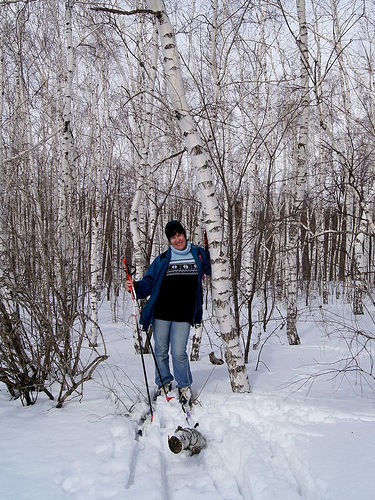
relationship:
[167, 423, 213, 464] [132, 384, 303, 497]
tree protruding from snow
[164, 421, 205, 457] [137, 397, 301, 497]
log sticking out of snow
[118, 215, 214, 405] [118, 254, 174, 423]
woman holding ski poles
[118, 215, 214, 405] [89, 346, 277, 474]
woman on snow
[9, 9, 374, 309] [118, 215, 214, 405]
trees surround woman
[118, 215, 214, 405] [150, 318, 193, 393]
woman wears blue jeans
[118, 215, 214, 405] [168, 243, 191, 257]
woman has turtle neck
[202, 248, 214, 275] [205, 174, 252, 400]
arm on tree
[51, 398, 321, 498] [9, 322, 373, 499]
snow on ground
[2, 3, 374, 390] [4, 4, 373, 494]
wooded area in picture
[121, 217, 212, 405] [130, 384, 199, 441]
she on skis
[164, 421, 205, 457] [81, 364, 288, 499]
log on ground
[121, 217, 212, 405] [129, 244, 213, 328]
she wears coat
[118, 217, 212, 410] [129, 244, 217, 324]
she wears sweater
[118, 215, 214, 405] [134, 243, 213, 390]
woman wears clothing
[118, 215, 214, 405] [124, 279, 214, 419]
woman holds skis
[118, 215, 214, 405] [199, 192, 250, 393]
woman holds tree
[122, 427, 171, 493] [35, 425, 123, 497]
tracks on snow